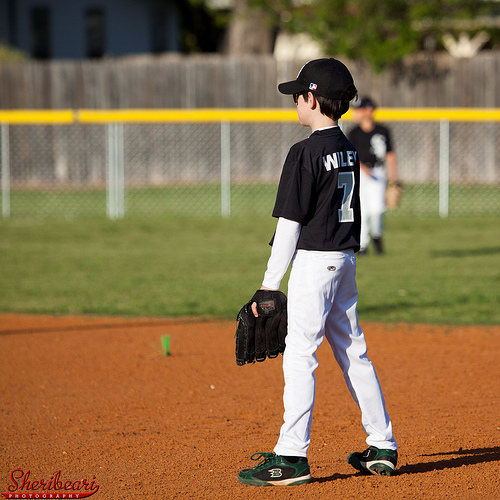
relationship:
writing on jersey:
[323, 147, 359, 224] [266, 125, 367, 252]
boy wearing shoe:
[233, 44, 418, 486] [345, 442, 395, 474]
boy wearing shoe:
[233, 44, 418, 486] [237, 453, 312, 487]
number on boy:
[335, 165, 365, 225] [203, 58, 451, 491]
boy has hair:
[233, 44, 418, 486] [324, 101, 341, 121]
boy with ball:
[233, 44, 418, 486] [208, 284, 269, 323]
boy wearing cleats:
[233, 44, 418, 486] [203, 454, 440, 487]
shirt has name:
[262, 126, 392, 261] [322, 149, 357, 170]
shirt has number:
[262, 126, 392, 261] [335, 170, 355, 224]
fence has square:
[0, 102, 499, 219] [2, 117, 77, 163]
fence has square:
[109, 102, 244, 231] [54, 146, 68, 159]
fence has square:
[0, 102, 499, 219] [451, 122, 498, 217]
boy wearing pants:
[233, 44, 418, 486] [240, 240, 407, 490]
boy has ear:
[233, 44, 418, 486] [292, 79, 328, 117]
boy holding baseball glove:
[233, 44, 418, 452] [234, 287, 288, 366]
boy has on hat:
[233, 44, 418, 486] [278, 55, 356, 100]